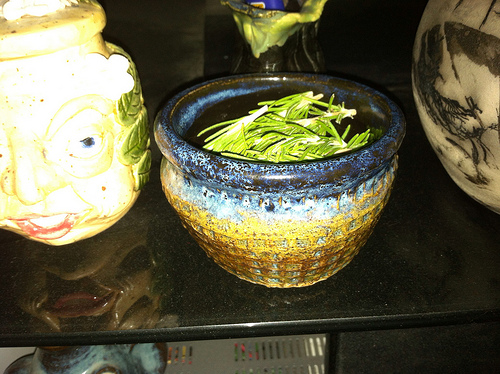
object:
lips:
[9, 214, 79, 239]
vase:
[0, 0, 151, 247]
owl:
[176, 47, 497, 294]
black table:
[2, 16, 500, 348]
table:
[2, 16, 495, 336]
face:
[0, 72, 117, 248]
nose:
[8, 126, 45, 204]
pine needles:
[199, 104, 361, 159]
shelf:
[0, 50, 499, 343]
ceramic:
[412, 0, 499, 214]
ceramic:
[0, 0, 153, 247]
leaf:
[229, 1, 327, 59]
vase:
[152, 70, 406, 288]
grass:
[195, 90, 372, 163]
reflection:
[8, 227, 174, 331]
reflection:
[215, 277, 338, 307]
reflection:
[227, 24, 325, 78]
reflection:
[383, 110, 496, 313]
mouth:
[10, 214, 76, 240]